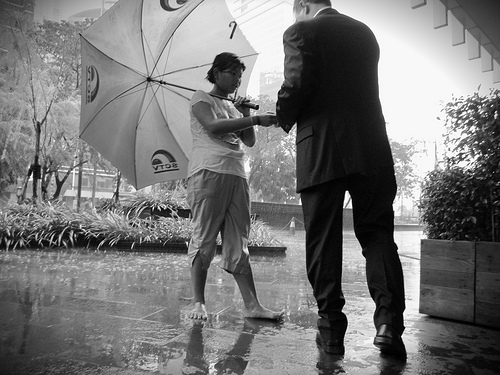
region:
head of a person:
[200, 50, 245, 105]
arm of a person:
[187, 98, 256, 153]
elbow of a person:
[205, 118, 234, 140]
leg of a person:
[164, 202, 242, 309]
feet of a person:
[189, 303, 215, 322]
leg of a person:
[219, 208, 275, 303]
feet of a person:
[230, 302, 300, 333]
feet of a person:
[297, 323, 352, 360]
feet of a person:
[369, 313, 429, 360]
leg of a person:
[342, 188, 427, 335]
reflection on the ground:
[183, 337, 205, 369]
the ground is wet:
[71, 271, 128, 321]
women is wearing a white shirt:
[191, 134, 222, 157]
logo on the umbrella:
[140, 143, 186, 178]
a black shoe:
[371, 327, 396, 349]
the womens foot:
[244, 302, 282, 327]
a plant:
[28, 200, 113, 235]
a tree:
[19, 79, 64, 196]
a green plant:
[430, 162, 491, 223]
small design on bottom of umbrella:
[73, 54, 113, 115]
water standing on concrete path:
[82, 295, 176, 369]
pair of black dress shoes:
[305, 302, 426, 357]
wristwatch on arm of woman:
[249, 111, 264, 126]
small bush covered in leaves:
[425, 90, 499, 228]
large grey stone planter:
[409, 233, 497, 344]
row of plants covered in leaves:
[1, 195, 181, 254]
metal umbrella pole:
[141, 69, 193, 96]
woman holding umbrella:
[171, 43, 288, 348]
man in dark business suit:
[275, 0, 435, 369]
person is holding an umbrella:
[58, 3, 285, 332]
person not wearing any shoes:
[180, 287, 285, 328]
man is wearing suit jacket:
[258, 1, 394, 191]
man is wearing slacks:
[293, 177, 410, 361]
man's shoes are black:
[309, 314, 408, 358]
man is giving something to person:
[74, 0, 410, 359]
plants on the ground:
[2, 174, 287, 256]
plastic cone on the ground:
[281, 210, 298, 239]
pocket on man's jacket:
[292, 122, 314, 152]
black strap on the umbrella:
[228, 18, 242, 42]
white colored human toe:
[201, 312, 208, 321]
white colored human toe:
[196, 313, 201, 322]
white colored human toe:
[192, 311, 197, 321]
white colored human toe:
[189, 312, 194, 319]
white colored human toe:
[186, 310, 191, 320]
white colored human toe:
[276, 308, 288, 316]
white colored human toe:
[281, 313, 290, 320]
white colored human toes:
[187, 310, 211, 321]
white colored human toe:
[271, 307, 286, 323]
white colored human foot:
[188, 303, 214, 323]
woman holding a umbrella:
[68, 5, 295, 339]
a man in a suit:
[259, 14, 430, 367]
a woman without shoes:
[166, 293, 313, 335]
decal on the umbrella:
[143, 145, 189, 190]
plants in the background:
[8, 186, 190, 261]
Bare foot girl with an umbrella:
[78, 2, 286, 322]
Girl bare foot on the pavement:
[189, 53, 287, 323]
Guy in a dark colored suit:
[278, 1, 406, 359]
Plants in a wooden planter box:
[421, 93, 498, 329]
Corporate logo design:
[149, 147, 180, 174]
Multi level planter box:
[13, 188, 289, 255]